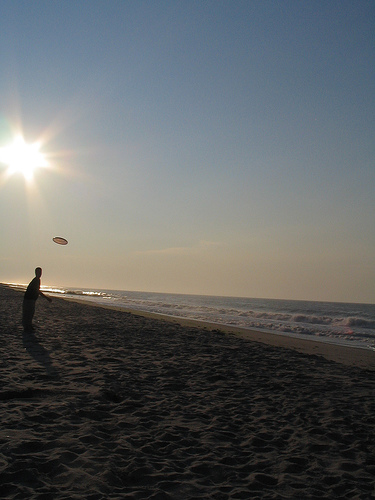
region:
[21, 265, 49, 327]
a boy standing on the beach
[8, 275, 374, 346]
ocean water rushing toward the shore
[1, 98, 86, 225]
the sun showing a starburst pattern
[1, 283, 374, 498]
a brown sandy beach in the evening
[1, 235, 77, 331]
a boy on the beach throwing a frisbee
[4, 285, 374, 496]
a sand on the ground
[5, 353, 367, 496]
footprints all over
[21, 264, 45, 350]
the man standing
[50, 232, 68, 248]
frisbee in the air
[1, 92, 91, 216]
the sun in air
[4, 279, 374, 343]
the ocean is big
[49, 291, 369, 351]
the seashore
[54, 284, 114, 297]
the water wave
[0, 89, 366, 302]
the clear sky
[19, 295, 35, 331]
dark colored pants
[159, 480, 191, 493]
footprint in the sand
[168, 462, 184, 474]
footprint in the sand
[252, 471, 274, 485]
footprint in the sand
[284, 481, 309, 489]
footprint in the sand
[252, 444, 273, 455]
footprint in the sand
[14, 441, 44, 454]
footprint in the sand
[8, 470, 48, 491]
footprint in the sand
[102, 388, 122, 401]
footprint in the sand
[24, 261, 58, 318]
man throwing a frisbee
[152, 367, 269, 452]
footprints in the sand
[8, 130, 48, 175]
sun shining brightly in the sky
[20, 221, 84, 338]
man throwing a frisbee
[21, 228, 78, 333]
man throwing a frisbee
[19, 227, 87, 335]
man throwing a frisbee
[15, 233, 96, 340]
man throwing a frisbee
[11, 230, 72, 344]
man throwing a frisbee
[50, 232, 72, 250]
the frisbee is white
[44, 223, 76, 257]
the frisbee is in the air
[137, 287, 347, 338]
the waves are crashing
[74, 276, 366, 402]
the waves are crashing on the beach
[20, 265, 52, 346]
the person is on the beach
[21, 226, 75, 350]
the person is catching a frisbee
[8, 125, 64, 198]
the sun is shining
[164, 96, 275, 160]
Clear blue skies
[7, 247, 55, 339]
a man at the beach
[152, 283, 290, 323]
Water in the ocean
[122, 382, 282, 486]
Sandy beach at the coastline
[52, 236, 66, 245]
frisbee flying in air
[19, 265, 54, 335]
person standing on sand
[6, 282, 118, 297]
wave crashing into beach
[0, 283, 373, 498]
sand is beige colored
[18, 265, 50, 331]
person throwing a frisbee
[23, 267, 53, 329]
person playing with frisbee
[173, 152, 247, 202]
the sky is clear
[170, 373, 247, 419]
the sand is brown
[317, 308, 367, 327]
the water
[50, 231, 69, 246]
a frisbee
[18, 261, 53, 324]
a person standing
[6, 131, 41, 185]
the sun is yellow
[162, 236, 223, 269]
clouds in the sky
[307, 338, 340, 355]
sand on the beach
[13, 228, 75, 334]
a person playing frisbee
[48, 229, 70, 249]
the frisbee is in the air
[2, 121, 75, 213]
teh sun has shiny rays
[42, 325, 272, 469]
the footprints on the sand